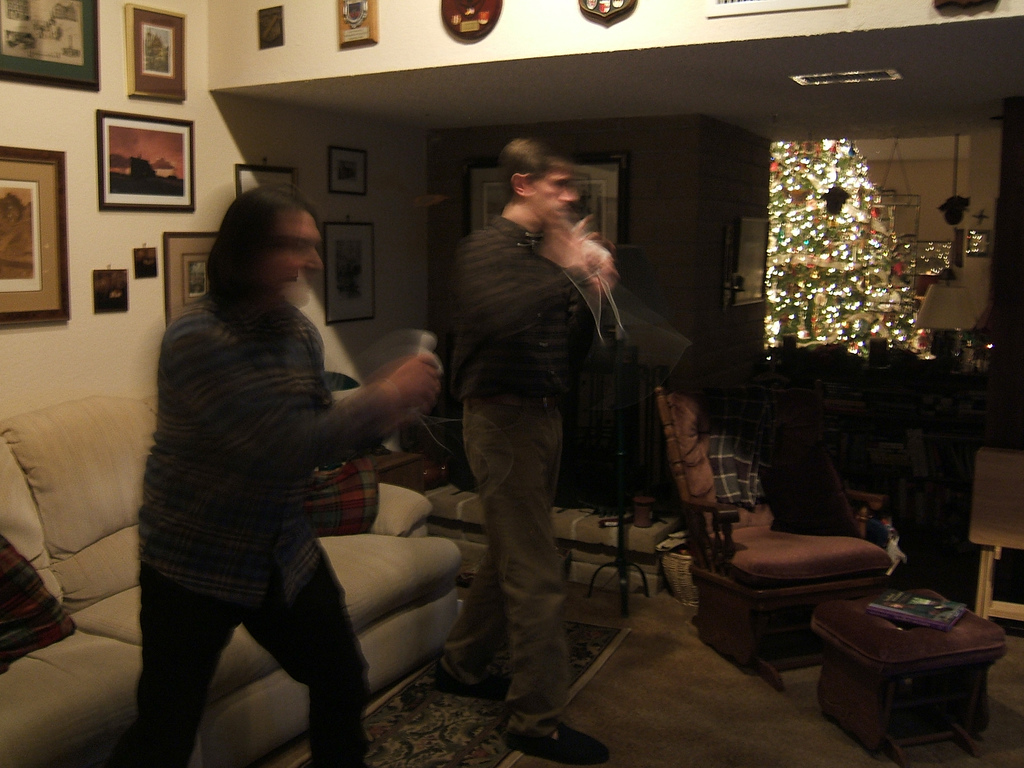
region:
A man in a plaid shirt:
[136, 181, 435, 766]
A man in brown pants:
[446, 149, 609, 766]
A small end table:
[820, 587, 1011, 740]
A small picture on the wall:
[100, 114, 198, 213]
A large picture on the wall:
[5, 143, 66, 336]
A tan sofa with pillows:
[0, 407, 136, 766]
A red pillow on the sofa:
[0, 531, 74, 662]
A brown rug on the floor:
[610, 655, 819, 766]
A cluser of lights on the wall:
[763, 145, 922, 360]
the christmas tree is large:
[762, 142, 934, 365]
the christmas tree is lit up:
[763, 145, 934, 370]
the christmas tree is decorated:
[765, 138, 939, 366]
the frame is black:
[93, 111, 196, 211]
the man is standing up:
[133, 177, 440, 760]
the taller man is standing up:
[460, 133, 615, 766]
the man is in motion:
[128, 181, 446, 766]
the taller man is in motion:
[462, 136, 624, 765]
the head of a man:
[190, 186, 347, 329]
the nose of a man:
[298, 239, 350, 288]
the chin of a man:
[266, 277, 324, 309]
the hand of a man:
[342, 356, 453, 443]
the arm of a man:
[137, 294, 371, 501]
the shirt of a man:
[140, 277, 356, 619]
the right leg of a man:
[140, 563, 245, 756]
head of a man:
[207, 177, 332, 332]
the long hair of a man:
[210, 212, 288, 296]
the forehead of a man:
[289, 203, 327, 238]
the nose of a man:
[272, 236, 342, 274]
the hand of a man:
[380, 347, 461, 411]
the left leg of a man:
[228, 566, 418, 732]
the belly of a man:
[134, 478, 318, 568]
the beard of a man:
[263, 271, 295, 326]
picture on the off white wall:
[0, 138, 70, 323]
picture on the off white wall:
[87, 100, 186, 205]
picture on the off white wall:
[117, 0, 185, 102]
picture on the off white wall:
[1, 0, 93, 93]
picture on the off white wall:
[157, 222, 206, 314]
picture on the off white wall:
[317, 137, 363, 195]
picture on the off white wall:
[315, 210, 370, 315]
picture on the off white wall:
[228, 159, 301, 198]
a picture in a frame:
[0, 138, 70, 332]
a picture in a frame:
[93, 103, 193, 211]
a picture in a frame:
[94, 256, 132, 320]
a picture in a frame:
[133, 244, 160, 276]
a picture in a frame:
[163, 234, 222, 323]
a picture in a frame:
[97, 106, 197, 206]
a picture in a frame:
[0, 7, 108, 96]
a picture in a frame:
[124, 4, 194, 100]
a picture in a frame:
[258, 4, 284, 42]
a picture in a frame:
[316, 222, 375, 327]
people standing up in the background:
[85, 95, 836, 712]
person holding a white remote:
[97, 151, 619, 765]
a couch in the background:
[21, 263, 647, 764]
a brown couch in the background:
[41, 322, 561, 744]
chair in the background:
[653, 417, 1021, 732]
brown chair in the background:
[637, 268, 958, 712]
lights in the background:
[719, 119, 1017, 417]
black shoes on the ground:
[451, 578, 683, 759]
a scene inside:
[60, 132, 778, 762]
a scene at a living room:
[40, 117, 971, 766]